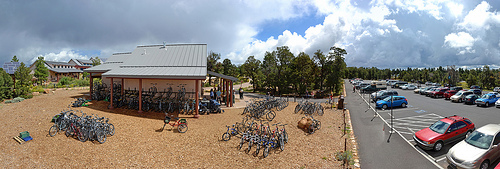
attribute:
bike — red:
[155, 102, 203, 140]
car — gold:
[447, 125, 499, 167]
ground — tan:
[125, 123, 177, 155]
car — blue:
[372, 94, 406, 110]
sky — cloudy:
[3, 2, 499, 69]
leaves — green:
[248, 44, 349, 96]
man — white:
[232, 90, 279, 130]